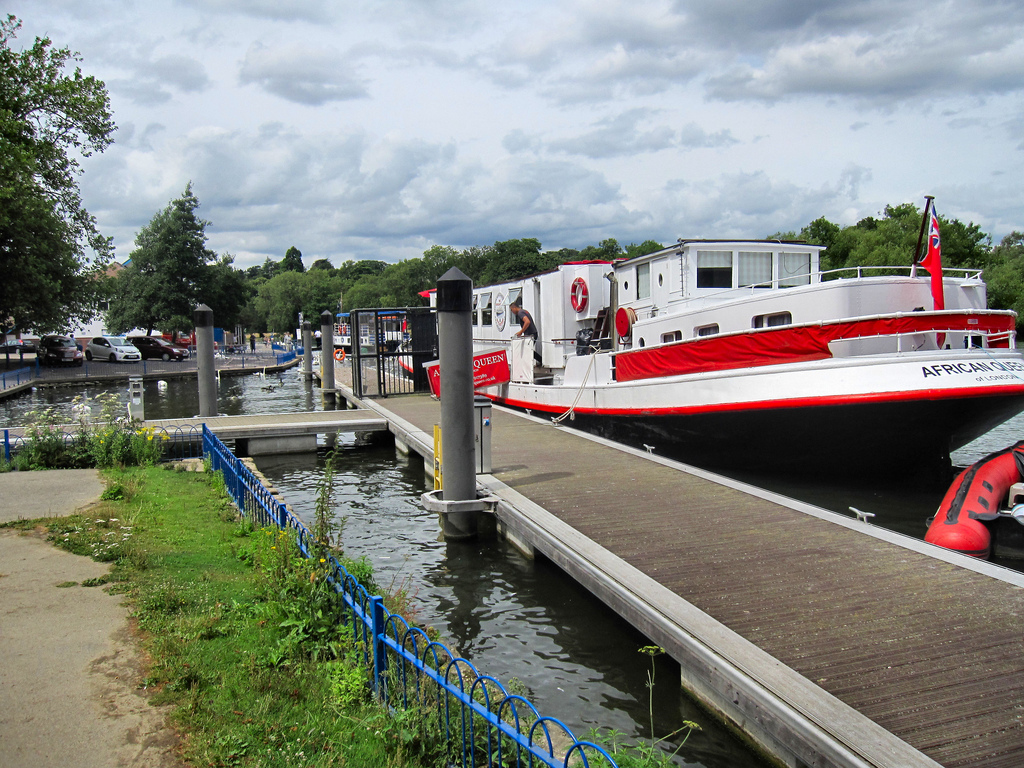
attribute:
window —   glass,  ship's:
[696, 253, 735, 284]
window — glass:
[755, 310, 801, 324]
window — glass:
[696, 322, 716, 336]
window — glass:
[696, 322, 725, 336]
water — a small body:
[315, 426, 631, 761]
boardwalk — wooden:
[352, 370, 1016, 764]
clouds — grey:
[0, 29, 999, 267]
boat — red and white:
[384, 219, 1020, 442]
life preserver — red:
[553, 268, 595, 314]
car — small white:
[64, 318, 164, 358]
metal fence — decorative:
[148, 398, 581, 755]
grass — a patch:
[95, 452, 441, 764]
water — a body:
[231, 381, 707, 755]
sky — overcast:
[2, 0, 860, 208]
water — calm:
[352, 536, 662, 755]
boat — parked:
[436, 208, 1003, 435]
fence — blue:
[241, 504, 475, 747]